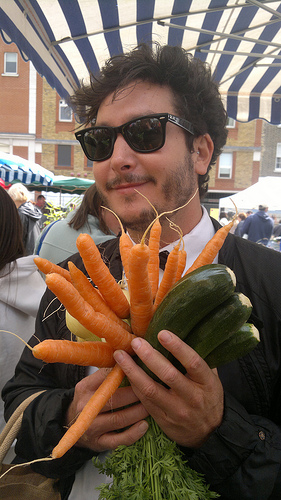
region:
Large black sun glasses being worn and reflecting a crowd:
[70, 115, 172, 155]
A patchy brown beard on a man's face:
[162, 161, 197, 205]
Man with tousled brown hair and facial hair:
[65, 45, 215, 222]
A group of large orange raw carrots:
[28, 234, 190, 320]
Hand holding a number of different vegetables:
[126, 335, 221, 436]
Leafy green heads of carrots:
[102, 446, 200, 498]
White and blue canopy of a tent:
[4, 154, 68, 188]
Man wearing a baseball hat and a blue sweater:
[241, 199, 276, 241]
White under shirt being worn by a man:
[156, 217, 220, 268]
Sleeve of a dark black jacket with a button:
[198, 396, 279, 497]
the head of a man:
[60, 34, 234, 234]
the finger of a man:
[93, 416, 150, 454]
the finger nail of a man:
[134, 417, 150, 435]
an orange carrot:
[49, 360, 128, 462]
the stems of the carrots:
[86, 408, 225, 499]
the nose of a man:
[107, 129, 137, 176]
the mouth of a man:
[101, 168, 161, 198]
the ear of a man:
[188, 125, 219, 178]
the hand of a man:
[108, 327, 229, 453]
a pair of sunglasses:
[69, 104, 206, 165]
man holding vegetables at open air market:
[2, 39, 279, 498]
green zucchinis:
[144, 262, 262, 371]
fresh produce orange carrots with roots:
[24, 216, 230, 480]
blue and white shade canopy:
[3, 0, 278, 129]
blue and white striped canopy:
[0, 149, 54, 189]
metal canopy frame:
[43, 0, 278, 91]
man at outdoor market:
[234, 202, 276, 247]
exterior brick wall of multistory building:
[1, 29, 258, 192]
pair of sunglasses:
[69, 111, 201, 161]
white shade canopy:
[216, 176, 273, 208]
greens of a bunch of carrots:
[92, 430, 211, 498]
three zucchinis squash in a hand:
[150, 258, 259, 375]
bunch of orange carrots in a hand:
[23, 215, 249, 366]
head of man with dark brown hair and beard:
[64, 43, 233, 230]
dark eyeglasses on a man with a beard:
[67, 108, 218, 176]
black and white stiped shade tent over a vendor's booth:
[11, 0, 276, 134]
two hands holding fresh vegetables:
[62, 327, 228, 456]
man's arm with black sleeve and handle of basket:
[3, 269, 77, 465]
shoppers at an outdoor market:
[214, 201, 275, 240]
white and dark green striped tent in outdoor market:
[0, 153, 57, 190]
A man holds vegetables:
[18, 44, 278, 493]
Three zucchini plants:
[143, 258, 257, 379]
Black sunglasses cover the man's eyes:
[70, 108, 211, 161]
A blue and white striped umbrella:
[0, 152, 53, 188]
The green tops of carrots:
[100, 443, 216, 497]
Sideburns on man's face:
[166, 161, 198, 211]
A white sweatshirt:
[0, 251, 43, 390]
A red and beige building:
[212, 116, 261, 186]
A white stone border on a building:
[26, 60, 37, 133]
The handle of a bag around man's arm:
[1, 383, 69, 498]